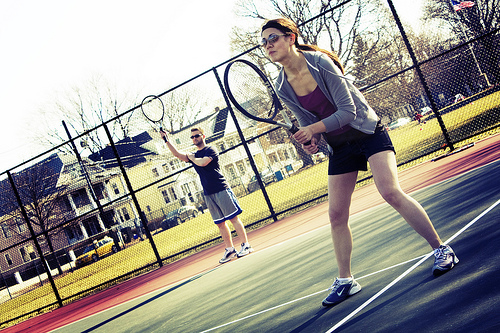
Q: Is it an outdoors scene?
A: Yes, it is outdoors.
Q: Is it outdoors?
A: Yes, it is outdoors.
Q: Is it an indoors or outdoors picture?
A: It is outdoors.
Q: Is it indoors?
A: No, it is outdoors.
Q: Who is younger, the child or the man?
A: The child is younger than the man.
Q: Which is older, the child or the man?
A: The man is older than the child.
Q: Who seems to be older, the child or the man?
A: The man is older than the child.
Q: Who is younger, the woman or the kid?
A: The kid is younger than the woman.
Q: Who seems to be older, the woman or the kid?
A: The woman is older than the kid.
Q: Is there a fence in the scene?
A: Yes, there is a fence.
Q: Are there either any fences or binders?
A: Yes, there is a fence.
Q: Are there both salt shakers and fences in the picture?
A: No, there is a fence but no salt shakers.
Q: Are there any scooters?
A: No, there are no scooters.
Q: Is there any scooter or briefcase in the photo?
A: No, there are no scooters or briefcases.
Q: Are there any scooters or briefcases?
A: No, there are no scooters or briefcases.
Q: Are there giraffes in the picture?
A: No, there are no giraffes.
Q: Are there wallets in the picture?
A: No, there are no wallets.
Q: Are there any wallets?
A: No, there are no wallets.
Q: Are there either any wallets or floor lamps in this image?
A: No, there are no wallets or floor lamps.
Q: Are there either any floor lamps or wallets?
A: No, there are no wallets or floor lamps.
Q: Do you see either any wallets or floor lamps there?
A: No, there are no wallets or floor lamps.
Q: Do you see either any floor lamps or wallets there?
A: No, there are no wallets or floor lamps.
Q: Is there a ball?
A: No, there are no balls.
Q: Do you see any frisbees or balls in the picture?
A: No, there are no balls or frisbees.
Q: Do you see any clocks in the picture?
A: No, there are no clocks.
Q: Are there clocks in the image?
A: No, there are no clocks.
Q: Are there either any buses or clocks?
A: No, there are no clocks or buses.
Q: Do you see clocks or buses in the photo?
A: No, there are no clocks or buses.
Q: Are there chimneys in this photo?
A: No, there are no chimneys.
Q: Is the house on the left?
A: Yes, the house is on the left of the image.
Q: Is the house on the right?
A: No, the house is on the left of the image.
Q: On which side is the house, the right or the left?
A: The house is on the left of the image.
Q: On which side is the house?
A: The house is on the left of the image.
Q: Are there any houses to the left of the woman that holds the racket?
A: Yes, there is a house to the left of the woman.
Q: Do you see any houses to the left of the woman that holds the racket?
A: Yes, there is a house to the left of the woman.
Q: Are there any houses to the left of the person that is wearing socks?
A: Yes, there is a house to the left of the woman.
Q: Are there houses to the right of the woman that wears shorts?
A: No, the house is to the left of the woman.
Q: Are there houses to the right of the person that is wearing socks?
A: No, the house is to the left of the woman.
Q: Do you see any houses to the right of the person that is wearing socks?
A: No, the house is to the left of the woman.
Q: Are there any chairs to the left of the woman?
A: No, there is a house to the left of the woman.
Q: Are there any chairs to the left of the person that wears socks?
A: No, there is a house to the left of the woman.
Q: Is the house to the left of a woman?
A: Yes, the house is to the left of a woman.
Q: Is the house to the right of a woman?
A: No, the house is to the left of a woman.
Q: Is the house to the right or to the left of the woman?
A: The house is to the left of the woman.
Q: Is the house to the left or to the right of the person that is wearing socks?
A: The house is to the left of the woman.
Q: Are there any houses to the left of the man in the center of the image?
A: Yes, there is a house to the left of the man.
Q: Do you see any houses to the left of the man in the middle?
A: Yes, there is a house to the left of the man.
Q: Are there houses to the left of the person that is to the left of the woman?
A: Yes, there is a house to the left of the man.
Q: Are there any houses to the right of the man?
A: No, the house is to the left of the man.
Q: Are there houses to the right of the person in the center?
A: No, the house is to the left of the man.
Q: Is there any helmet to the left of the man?
A: No, there is a house to the left of the man.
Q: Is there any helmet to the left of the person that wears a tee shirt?
A: No, there is a house to the left of the man.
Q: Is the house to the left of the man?
A: Yes, the house is to the left of the man.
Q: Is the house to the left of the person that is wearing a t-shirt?
A: Yes, the house is to the left of the man.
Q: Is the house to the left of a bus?
A: No, the house is to the left of the man.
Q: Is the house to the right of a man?
A: No, the house is to the left of a man.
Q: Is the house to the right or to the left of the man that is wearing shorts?
A: The house is to the left of the man.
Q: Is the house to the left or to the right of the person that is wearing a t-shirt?
A: The house is to the left of the man.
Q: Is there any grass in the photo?
A: Yes, there is grass.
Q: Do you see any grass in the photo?
A: Yes, there is grass.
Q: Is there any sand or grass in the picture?
A: Yes, there is grass.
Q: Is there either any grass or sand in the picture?
A: Yes, there is grass.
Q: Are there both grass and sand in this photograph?
A: No, there is grass but no sand.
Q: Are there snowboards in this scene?
A: No, there are no snowboards.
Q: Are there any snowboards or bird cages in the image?
A: No, there are no snowboards or bird cages.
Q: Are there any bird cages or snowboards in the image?
A: No, there are no snowboards or bird cages.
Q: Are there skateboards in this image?
A: No, there are no skateboards.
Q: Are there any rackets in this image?
A: Yes, there is a racket.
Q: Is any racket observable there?
A: Yes, there is a racket.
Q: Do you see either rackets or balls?
A: Yes, there is a racket.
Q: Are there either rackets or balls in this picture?
A: Yes, there is a racket.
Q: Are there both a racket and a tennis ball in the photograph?
A: No, there is a racket but no tennis balls.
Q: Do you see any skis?
A: No, there are no skis.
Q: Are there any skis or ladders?
A: No, there are no skis or ladders.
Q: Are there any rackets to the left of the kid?
A: Yes, there is a racket to the left of the kid.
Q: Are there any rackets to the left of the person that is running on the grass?
A: Yes, there is a racket to the left of the kid.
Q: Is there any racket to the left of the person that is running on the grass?
A: Yes, there is a racket to the left of the kid.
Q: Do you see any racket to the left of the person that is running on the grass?
A: Yes, there is a racket to the left of the kid.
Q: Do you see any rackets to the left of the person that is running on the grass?
A: Yes, there is a racket to the left of the kid.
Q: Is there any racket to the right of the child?
A: No, the racket is to the left of the child.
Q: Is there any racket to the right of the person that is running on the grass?
A: No, the racket is to the left of the child.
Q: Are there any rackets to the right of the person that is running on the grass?
A: No, the racket is to the left of the child.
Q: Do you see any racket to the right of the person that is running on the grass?
A: No, the racket is to the left of the child.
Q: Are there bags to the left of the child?
A: No, there is a racket to the left of the child.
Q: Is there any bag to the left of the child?
A: No, there is a racket to the left of the child.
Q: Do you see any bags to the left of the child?
A: No, there is a racket to the left of the child.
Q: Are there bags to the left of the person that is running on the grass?
A: No, there is a racket to the left of the child.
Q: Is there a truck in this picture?
A: No, there are no trucks.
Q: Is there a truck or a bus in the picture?
A: No, there are no trucks or buses.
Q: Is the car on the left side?
A: Yes, the car is on the left of the image.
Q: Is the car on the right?
A: No, the car is on the left of the image.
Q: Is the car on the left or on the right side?
A: The car is on the left of the image.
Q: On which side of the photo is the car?
A: The car is on the left of the image.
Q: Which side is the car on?
A: The car is on the left of the image.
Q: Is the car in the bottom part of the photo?
A: Yes, the car is in the bottom of the image.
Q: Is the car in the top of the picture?
A: No, the car is in the bottom of the image.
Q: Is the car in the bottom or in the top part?
A: The car is in the bottom of the image.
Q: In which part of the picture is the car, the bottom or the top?
A: The car is in the bottom of the image.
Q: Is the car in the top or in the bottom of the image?
A: The car is in the bottom of the image.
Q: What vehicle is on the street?
A: The vehicle is a car.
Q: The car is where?
A: The car is on the street.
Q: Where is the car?
A: The car is on the street.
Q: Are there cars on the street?
A: Yes, there is a car on the street.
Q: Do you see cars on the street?
A: Yes, there is a car on the street.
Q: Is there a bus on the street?
A: No, there is a car on the street.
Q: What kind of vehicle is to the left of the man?
A: The vehicle is a car.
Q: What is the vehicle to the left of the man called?
A: The vehicle is a car.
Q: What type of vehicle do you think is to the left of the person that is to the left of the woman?
A: The vehicle is a car.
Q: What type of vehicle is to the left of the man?
A: The vehicle is a car.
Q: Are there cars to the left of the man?
A: Yes, there is a car to the left of the man.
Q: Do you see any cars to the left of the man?
A: Yes, there is a car to the left of the man.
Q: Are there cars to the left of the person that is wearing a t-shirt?
A: Yes, there is a car to the left of the man.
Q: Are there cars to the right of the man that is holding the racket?
A: No, the car is to the left of the man.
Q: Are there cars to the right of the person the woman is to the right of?
A: No, the car is to the left of the man.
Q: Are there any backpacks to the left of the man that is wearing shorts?
A: No, there is a car to the left of the man.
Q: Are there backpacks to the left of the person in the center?
A: No, there is a car to the left of the man.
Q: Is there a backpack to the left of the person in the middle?
A: No, there is a car to the left of the man.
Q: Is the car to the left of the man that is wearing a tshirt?
A: Yes, the car is to the left of the man.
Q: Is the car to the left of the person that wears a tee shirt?
A: Yes, the car is to the left of the man.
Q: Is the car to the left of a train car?
A: No, the car is to the left of the man.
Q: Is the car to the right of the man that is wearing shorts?
A: No, the car is to the left of the man.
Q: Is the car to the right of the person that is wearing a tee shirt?
A: No, the car is to the left of the man.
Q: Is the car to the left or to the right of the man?
A: The car is to the left of the man.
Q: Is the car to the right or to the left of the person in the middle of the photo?
A: The car is to the left of the man.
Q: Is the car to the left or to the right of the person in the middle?
A: The car is to the left of the man.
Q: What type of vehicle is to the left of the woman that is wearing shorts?
A: The vehicle is a car.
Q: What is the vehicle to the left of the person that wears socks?
A: The vehicle is a car.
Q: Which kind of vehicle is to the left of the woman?
A: The vehicle is a car.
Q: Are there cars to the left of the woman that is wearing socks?
A: Yes, there is a car to the left of the woman.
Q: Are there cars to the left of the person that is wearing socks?
A: Yes, there is a car to the left of the woman.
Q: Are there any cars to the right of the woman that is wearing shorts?
A: No, the car is to the left of the woman.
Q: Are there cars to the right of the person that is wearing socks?
A: No, the car is to the left of the woman.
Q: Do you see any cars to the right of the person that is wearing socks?
A: No, the car is to the left of the woman.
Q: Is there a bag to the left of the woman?
A: No, there is a car to the left of the woman.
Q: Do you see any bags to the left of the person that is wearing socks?
A: No, there is a car to the left of the woman.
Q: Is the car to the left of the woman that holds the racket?
A: Yes, the car is to the left of the woman.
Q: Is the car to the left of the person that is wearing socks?
A: Yes, the car is to the left of the woman.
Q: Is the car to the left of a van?
A: No, the car is to the left of the woman.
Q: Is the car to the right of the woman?
A: No, the car is to the left of the woman.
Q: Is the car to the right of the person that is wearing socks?
A: No, the car is to the left of the woman.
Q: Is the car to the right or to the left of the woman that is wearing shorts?
A: The car is to the left of the woman.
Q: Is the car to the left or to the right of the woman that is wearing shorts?
A: The car is to the left of the woman.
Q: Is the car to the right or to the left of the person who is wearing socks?
A: The car is to the left of the woman.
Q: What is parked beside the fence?
A: The car is parked beside the fence.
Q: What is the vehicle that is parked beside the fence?
A: The vehicle is a car.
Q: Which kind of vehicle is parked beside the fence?
A: The vehicle is a car.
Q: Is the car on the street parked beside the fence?
A: Yes, the car is parked beside the fence.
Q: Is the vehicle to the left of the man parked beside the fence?
A: Yes, the car is parked beside the fence.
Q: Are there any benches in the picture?
A: No, there are no benches.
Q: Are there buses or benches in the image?
A: No, there are no benches or buses.